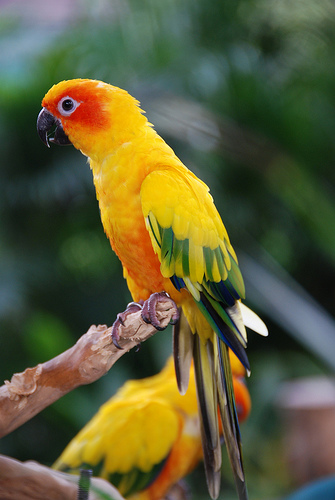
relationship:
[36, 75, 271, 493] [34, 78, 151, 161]
bird has head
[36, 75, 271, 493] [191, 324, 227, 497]
bird has tail feather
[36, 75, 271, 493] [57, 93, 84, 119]
bird has eye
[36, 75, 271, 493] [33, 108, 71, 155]
bird has beak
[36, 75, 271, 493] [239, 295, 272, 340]
bird has feather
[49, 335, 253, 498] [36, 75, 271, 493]
bird behind bird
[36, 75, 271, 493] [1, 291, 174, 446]
bird standing on perch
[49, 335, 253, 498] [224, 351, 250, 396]
bird has face